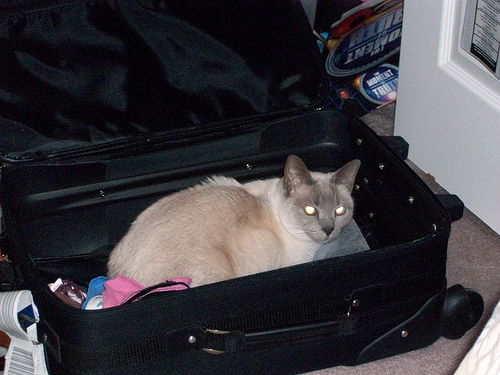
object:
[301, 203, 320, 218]
glare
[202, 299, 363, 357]
handle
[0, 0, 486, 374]
bag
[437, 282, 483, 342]
wheel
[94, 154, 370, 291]
cat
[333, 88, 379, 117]
man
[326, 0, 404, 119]
box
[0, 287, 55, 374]
tag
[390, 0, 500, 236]
door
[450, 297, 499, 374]
mattress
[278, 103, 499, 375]
floor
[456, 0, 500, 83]
window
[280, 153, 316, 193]
ear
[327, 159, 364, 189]
ear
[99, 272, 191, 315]
clothing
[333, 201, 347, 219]
left eye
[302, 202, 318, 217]
right eye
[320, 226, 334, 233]
nose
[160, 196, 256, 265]
fur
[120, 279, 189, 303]
lining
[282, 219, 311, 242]
whiskers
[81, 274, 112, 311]
clothing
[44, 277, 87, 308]
clothing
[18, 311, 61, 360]
handle